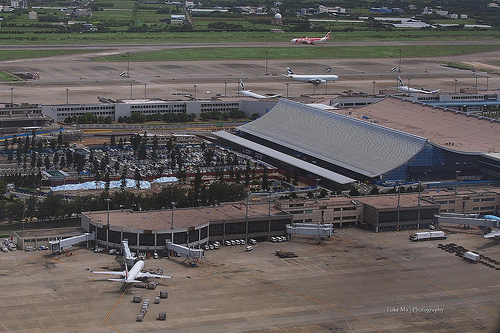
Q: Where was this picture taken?
A: Airport.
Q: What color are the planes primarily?
A: White.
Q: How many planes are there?
A: Five.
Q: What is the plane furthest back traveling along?
A: Runway.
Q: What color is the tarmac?
A: Gray.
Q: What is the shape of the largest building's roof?
A: Sloped.